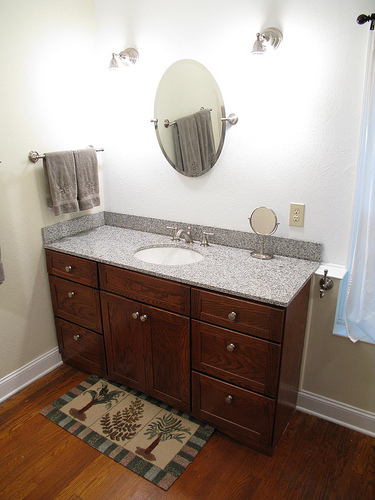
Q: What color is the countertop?
A: Gray.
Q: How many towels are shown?
A: Two.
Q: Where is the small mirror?
A: On the sink.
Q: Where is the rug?
A: On the floor.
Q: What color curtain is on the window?
A: White.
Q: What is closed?
A: The cupboards.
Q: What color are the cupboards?
A: Brown.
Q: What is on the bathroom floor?
A: A rug.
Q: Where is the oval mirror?
A: On the wall.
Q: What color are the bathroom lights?
A: Silver.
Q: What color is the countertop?
A: Gray.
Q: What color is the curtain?
A: White.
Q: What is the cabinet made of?
A: Wood.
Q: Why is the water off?
A: There isn't anyone using it.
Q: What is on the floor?
A: A small rug.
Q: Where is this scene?
A: A bathroom.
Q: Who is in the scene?
A: No one.